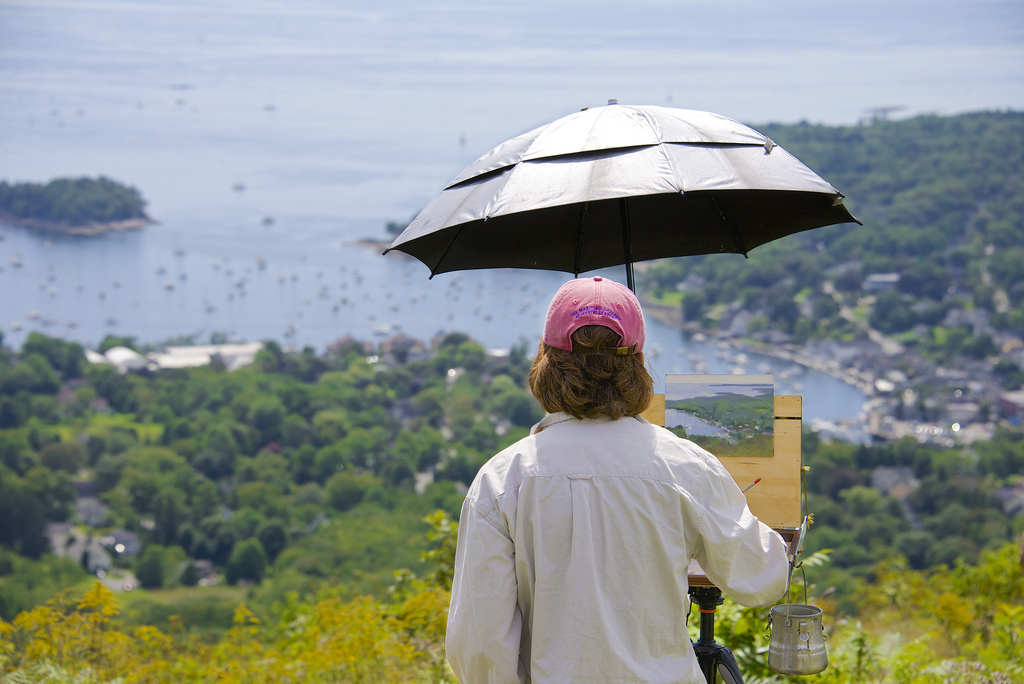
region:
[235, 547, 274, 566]
tree on the hill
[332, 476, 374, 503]
tree on the hill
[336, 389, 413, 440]
tree on the hill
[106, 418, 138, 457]
tree on the hill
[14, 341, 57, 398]
tree on the hill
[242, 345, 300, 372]
tree on the hill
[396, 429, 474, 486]
tree on the hill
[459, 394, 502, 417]
tree on the hill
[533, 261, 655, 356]
THE GIRL'S HAT IS PINK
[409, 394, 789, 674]
THE GIRL IS WEARING A LONG SLEEVED SHIRT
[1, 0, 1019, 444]
THE WATER IS BLUE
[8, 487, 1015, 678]
THE WEEDS ARE YELLOW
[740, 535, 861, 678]
THE BUCKET IS SHINY AND SILVER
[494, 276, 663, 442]
THE GIRL HAS BROWN HAIR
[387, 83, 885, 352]
THE UMBRELLA IS OPEN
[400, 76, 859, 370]
THE UMBRELLA IS BLACK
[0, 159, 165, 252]
THE ISLAND IS COVERED IN GREEN TREES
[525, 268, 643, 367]
man wearing ball cap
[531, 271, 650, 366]
mans cap is pink